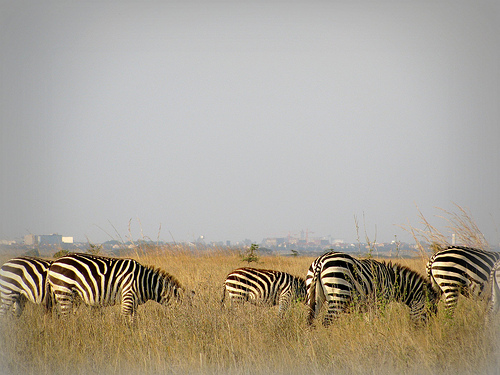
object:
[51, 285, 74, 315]
stripe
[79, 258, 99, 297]
stripe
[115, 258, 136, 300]
stripe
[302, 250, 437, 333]
stripes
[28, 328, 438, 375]
ground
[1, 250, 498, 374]
field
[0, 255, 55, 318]
animal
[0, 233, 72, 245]
building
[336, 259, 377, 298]
fur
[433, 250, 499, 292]
zebra's fur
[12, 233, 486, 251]
cities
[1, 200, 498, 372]
grass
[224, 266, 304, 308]
stripes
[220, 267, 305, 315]
zebra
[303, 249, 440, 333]
zebra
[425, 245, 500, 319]
zebra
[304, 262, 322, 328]
tail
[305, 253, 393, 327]
body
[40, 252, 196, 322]
zebra